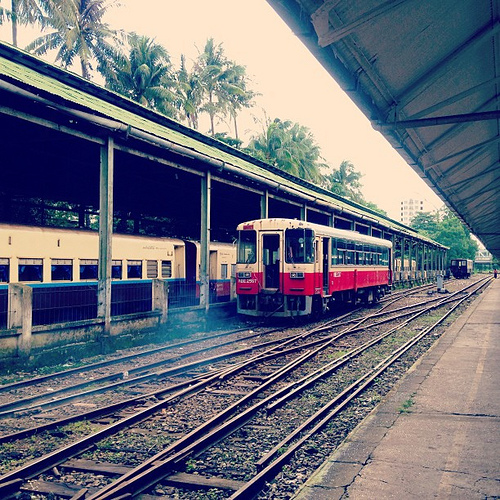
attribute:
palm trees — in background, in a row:
[1, 1, 384, 217]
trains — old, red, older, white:
[236, 214, 397, 324]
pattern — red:
[235, 268, 392, 300]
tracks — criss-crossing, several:
[2, 271, 493, 500]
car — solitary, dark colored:
[450, 254, 477, 281]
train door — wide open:
[258, 227, 283, 290]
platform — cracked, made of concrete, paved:
[277, 273, 498, 500]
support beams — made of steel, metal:
[87, 135, 454, 358]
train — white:
[2, 219, 186, 332]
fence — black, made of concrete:
[2, 274, 239, 359]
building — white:
[397, 192, 425, 228]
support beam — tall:
[93, 139, 118, 325]